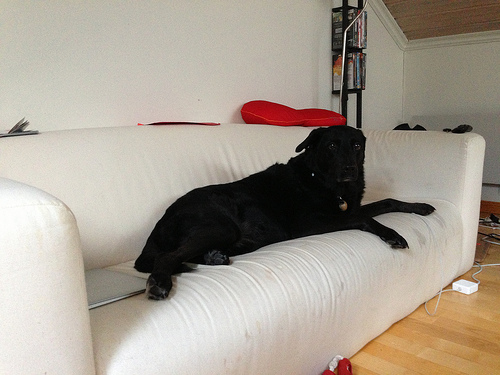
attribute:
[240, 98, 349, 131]
pillow — red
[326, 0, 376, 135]
shelf — black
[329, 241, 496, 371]
floors — tan, hardwood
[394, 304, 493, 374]
floor — brown, wooden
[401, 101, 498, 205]
shadow — black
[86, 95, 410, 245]
dog — black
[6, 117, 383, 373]
couch — white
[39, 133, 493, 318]
couch — wrinkled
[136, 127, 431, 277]
dog — black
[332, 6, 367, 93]
dvds — in the picture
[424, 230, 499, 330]
power cord — white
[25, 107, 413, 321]
couch — white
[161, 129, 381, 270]
dog — black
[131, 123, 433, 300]
dog — black